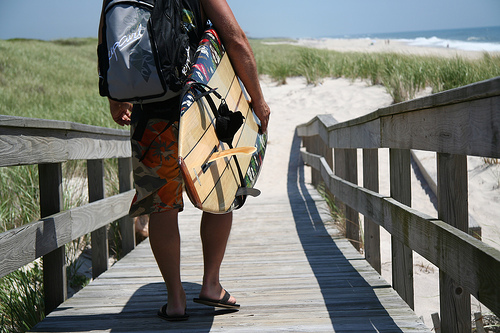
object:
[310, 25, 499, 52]
water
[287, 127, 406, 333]
shadows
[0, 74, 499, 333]
bridge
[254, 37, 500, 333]
sand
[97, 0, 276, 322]
man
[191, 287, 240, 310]
slippers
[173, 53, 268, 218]
surfboard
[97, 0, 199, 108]
backpack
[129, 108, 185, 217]
shorts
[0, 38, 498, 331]
grass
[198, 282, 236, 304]
feet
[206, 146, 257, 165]
fin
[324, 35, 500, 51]
waves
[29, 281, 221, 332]
shadow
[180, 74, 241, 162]
black lines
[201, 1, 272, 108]
right arm